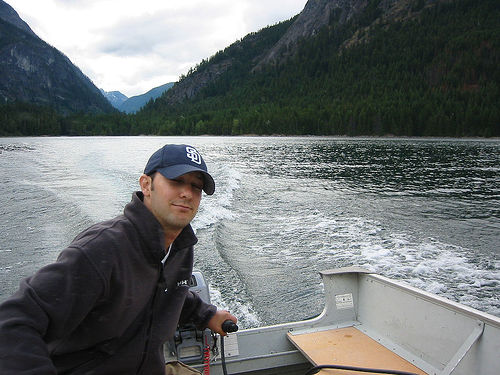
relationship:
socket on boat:
[331, 290, 358, 310] [188, 270, 500, 375]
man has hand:
[6, 137, 252, 374] [210, 309, 238, 341]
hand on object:
[210, 309, 238, 341] [221, 317, 239, 333]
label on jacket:
[175, 279, 191, 289] [40, 197, 196, 368]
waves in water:
[210, 205, 279, 310] [210, 142, 497, 278]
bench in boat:
[292, 333, 410, 374] [188, 270, 500, 375]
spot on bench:
[341, 331, 358, 343] [292, 333, 410, 374]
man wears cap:
[6, 137, 252, 374] [146, 143, 220, 196]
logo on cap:
[183, 146, 205, 166] [146, 143, 220, 196]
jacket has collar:
[40, 197, 196, 368] [123, 200, 168, 258]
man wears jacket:
[6, 137, 252, 374] [40, 197, 196, 368]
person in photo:
[6, 137, 252, 374] [5, 4, 499, 370]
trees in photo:
[163, 94, 477, 136] [5, 4, 499, 370]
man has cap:
[6, 137, 252, 374] [146, 143, 220, 196]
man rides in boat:
[6, 137, 252, 374] [188, 270, 500, 375]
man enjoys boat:
[6, 137, 252, 374] [188, 270, 500, 375]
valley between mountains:
[80, 64, 182, 142] [163, 2, 495, 141]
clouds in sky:
[114, 58, 163, 84] [38, 5, 237, 56]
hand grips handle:
[210, 309, 238, 341] [221, 317, 239, 333]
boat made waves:
[188, 270, 500, 375] [210, 205, 279, 310]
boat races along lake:
[188, 270, 500, 375] [210, 142, 497, 278]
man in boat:
[6, 137, 252, 374] [188, 270, 500, 375]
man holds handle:
[6, 137, 252, 374] [221, 317, 239, 333]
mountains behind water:
[163, 2, 495, 141] [210, 142, 497, 278]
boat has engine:
[188, 270, 500, 375] [192, 270, 214, 314]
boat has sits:
[188, 270, 500, 375] [292, 333, 410, 374]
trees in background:
[163, 94, 477, 136] [163, 2, 495, 141]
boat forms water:
[188, 270, 500, 375] [210, 142, 497, 278]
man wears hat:
[6, 137, 252, 374] [146, 143, 220, 196]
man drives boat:
[6, 137, 252, 374] [188, 270, 500, 375]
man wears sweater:
[6, 137, 252, 374] [40, 197, 196, 368]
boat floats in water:
[188, 270, 500, 375] [210, 142, 497, 278]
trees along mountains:
[163, 94, 477, 136] [163, 2, 495, 141]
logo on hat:
[183, 146, 205, 166] [146, 143, 220, 196]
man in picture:
[6, 137, 252, 374] [5, 4, 499, 370]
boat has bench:
[188, 270, 500, 375] [292, 333, 410, 374]